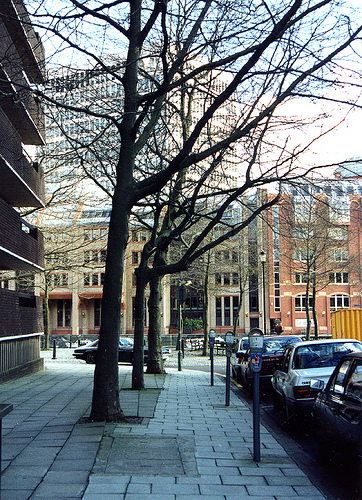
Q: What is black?
A: Car.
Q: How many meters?
A: Three.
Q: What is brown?
A: Building.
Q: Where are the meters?
A: Along the sidewalk.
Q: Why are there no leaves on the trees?
A: It is winter.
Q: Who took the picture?
A: Man.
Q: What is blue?
A: Sky.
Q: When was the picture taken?
A: Daytime.